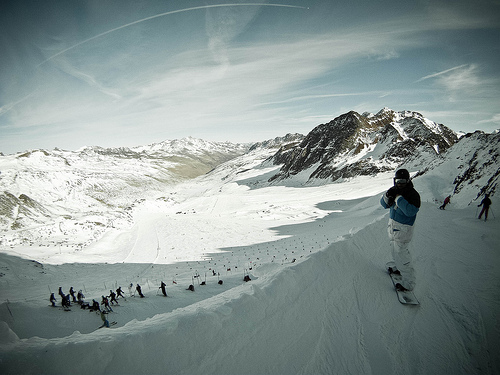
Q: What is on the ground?
A: Snow.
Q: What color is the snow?
A: White.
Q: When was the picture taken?
A: Daytime.